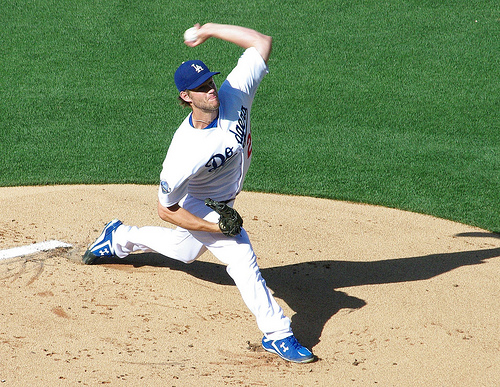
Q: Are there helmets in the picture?
A: No, there are no helmets.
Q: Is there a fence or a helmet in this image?
A: No, there are no helmets or fences.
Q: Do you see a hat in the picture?
A: Yes, there is a hat.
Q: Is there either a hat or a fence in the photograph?
A: Yes, there is a hat.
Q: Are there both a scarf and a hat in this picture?
A: No, there is a hat but no scarves.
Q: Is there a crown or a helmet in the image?
A: No, there are no helmets or crowns.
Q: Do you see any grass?
A: Yes, there is grass.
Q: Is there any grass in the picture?
A: Yes, there is grass.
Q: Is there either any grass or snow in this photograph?
A: Yes, there is grass.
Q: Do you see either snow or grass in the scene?
A: Yes, there is grass.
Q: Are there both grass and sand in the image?
A: Yes, there are both grass and sand.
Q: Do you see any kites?
A: No, there are no kites.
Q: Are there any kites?
A: No, there are no kites.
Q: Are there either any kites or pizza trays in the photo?
A: No, there are no kites or pizza trays.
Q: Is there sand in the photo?
A: Yes, there is sand.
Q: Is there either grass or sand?
A: Yes, there is sand.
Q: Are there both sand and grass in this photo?
A: Yes, there are both sand and grass.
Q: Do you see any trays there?
A: No, there are no trays.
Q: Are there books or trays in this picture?
A: No, there are no trays or books.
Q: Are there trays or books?
A: No, there are no trays or books.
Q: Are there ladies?
A: No, there are no ladies.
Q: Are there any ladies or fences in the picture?
A: No, there are no ladies or fences.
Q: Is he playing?
A: Yes, the man is playing.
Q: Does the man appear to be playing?
A: Yes, the man is playing.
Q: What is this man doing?
A: The man is playing.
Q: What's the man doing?
A: The man is playing.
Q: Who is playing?
A: The man is playing.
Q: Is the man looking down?
A: No, the man is playing.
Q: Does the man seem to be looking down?
A: No, the man is playing.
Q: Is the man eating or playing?
A: The man is playing.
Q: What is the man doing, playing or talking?
A: The man is playing.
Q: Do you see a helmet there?
A: No, there are no helmets.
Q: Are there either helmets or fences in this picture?
A: No, there are no helmets or fences.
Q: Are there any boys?
A: No, there are no boys.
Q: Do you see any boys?
A: No, there are no boys.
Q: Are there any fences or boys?
A: No, there are no boys or fences.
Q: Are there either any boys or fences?
A: No, there are no boys or fences.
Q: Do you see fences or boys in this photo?
A: No, there are no boys or fences.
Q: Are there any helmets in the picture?
A: No, there are no helmets.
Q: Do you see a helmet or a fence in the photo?
A: No, there are no helmets or fences.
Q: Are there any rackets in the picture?
A: No, there are no rackets.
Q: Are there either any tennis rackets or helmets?
A: No, there are no tennis rackets or helmets.